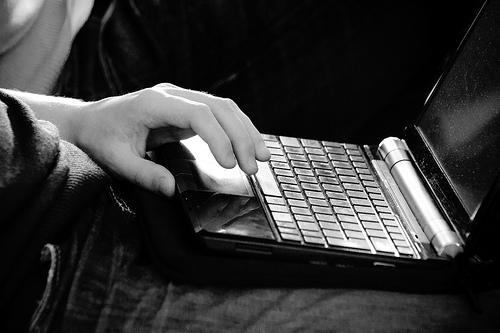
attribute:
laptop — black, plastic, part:
[145, 0, 498, 287]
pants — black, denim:
[8, 180, 499, 331]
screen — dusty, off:
[415, 2, 499, 218]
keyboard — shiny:
[251, 131, 415, 258]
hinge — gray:
[377, 136, 464, 259]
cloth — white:
[1, 0, 95, 95]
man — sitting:
[1, 81, 496, 333]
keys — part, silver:
[251, 131, 418, 260]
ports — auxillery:
[313, 259, 397, 271]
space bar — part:
[256, 160, 281, 196]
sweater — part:
[1, 91, 113, 306]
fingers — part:
[191, 95, 271, 174]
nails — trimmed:
[157, 143, 268, 193]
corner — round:
[192, 228, 208, 249]